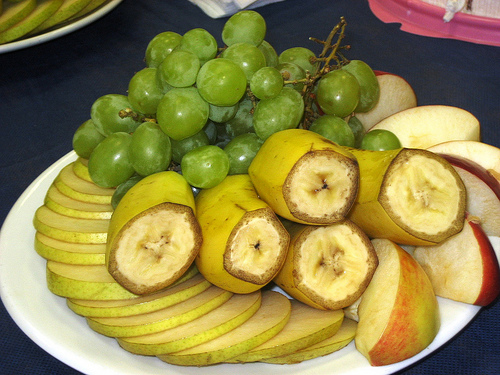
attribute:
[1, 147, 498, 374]
white plate —  white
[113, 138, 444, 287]
bananas —  yellow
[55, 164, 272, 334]
apples —  green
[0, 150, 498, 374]
plate — round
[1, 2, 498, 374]
table — blue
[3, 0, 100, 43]
fruit —   yellow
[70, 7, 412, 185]
green grapes —  green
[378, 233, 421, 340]
slice — white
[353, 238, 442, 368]
slice —  apple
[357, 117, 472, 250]
banana — browning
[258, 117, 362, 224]
banana — browning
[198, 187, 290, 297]
banana — browning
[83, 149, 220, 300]
banana — browning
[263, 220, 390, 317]
banana — browning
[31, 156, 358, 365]
apples —  sliced,  Green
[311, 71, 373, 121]
grape — green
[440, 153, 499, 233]
apple —  red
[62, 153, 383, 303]
banana —  yellow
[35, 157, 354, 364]
fruit —  sliced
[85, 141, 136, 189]
grape — green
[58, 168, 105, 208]
apple — green